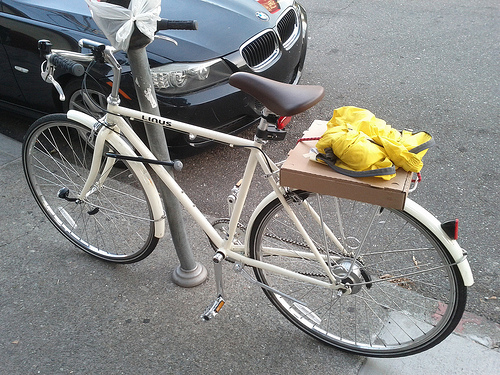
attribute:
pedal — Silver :
[183, 284, 251, 343]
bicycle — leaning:
[41, 17, 484, 353]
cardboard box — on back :
[265, 101, 441, 230]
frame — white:
[104, 100, 275, 288]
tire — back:
[207, 163, 476, 360]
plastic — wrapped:
[80, 7, 167, 53]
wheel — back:
[232, 170, 488, 373]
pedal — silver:
[172, 260, 237, 338]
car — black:
[72, 12, 302, 164]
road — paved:
[201, 50, 466, 223]